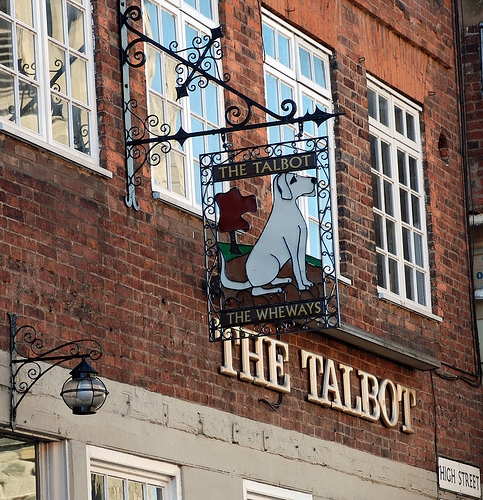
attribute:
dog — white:
[214, 169, 331, 303]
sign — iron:
[120, 11, 351, 329]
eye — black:
[285, 171, 302, 186]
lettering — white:
[203, 311, 444, 447]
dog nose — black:
[309, 174, 317, 185]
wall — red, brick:
[92, 267, 178, 362]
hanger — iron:
[9, 315, 104, 400]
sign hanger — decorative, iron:
[122, 5, 353, 218]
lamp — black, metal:
[7, 312, 109, 430]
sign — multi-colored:
[196, 135, 342, 341]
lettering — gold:
[214, 318, 417, 433]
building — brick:
[2, 1, 482, 498]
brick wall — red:
[2, 3, 482, 483]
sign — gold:
[184, 122, 379, 332]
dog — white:
[217, 170, 319, 301]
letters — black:
[437, 464, 480, 491]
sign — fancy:
[199, 129, 334, 340]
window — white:
[354, 69, 449, 320]